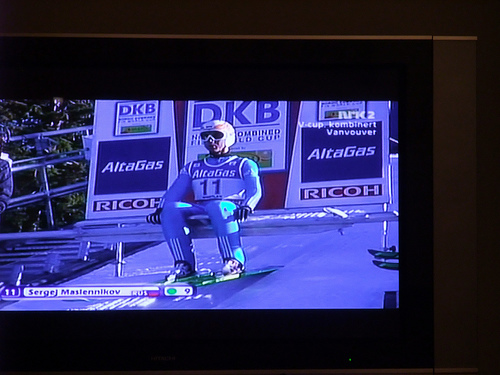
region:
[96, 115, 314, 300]
a skier on a bench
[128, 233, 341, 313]
green skis on feet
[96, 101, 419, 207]
advertisements behind skier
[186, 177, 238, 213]
nubmer 11 on shirt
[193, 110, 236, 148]
white helmet on head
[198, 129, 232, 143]
white goggles on face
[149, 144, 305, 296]
a blue and white outfit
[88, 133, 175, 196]
blue sign with white letters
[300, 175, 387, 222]
red sign with white letters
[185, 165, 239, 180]
white letters on shirt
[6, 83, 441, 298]
a picture of a snowboarder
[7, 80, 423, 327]
this snowboarder is on a television screen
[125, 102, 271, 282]
the man is sitting on a platform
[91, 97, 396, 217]
advertisements and sponsors for the skateboarder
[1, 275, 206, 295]
the name of the skier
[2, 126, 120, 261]
setps besides the snowboarder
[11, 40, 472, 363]
this is a monitor of a snowboarder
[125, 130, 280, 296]
the snowboarder is wearing blue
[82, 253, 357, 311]
the snow is in the area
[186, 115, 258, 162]
he has on a helmet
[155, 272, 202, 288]
the green ski of the skier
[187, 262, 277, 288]
the green ski of the skier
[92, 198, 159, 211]
the white RICOH word on the sign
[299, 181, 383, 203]
the white RICOH word on the sign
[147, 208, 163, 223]
the blue and white glove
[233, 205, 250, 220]
the blue and white glove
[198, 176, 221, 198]
the large blue number 11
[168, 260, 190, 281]
a blue and white ski boot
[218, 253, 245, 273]
a blue and white ski boot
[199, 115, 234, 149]
a white ski helmet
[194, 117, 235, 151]
person has white helmet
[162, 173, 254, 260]
person has blue suit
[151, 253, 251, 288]
person has black shoes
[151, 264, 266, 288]
person is on skis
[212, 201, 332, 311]
person at top of ski jump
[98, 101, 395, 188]
advert signs behind man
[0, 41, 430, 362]
black frame on tv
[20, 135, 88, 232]
silver rail near man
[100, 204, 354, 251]
person is sitting down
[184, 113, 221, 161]
person wears black goggles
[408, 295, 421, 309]
part of a screen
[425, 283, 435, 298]
edge of a screen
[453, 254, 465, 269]
part of a wall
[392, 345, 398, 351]
edge of a screen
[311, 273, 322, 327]
part of a screen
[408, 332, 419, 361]
edge of a screen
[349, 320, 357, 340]
part of a screen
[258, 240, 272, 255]
edge of a screen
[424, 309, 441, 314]
side of a wall